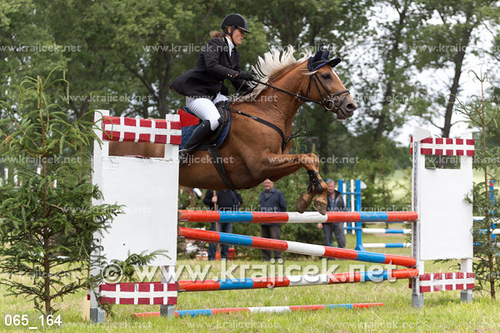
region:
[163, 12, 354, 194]
person riding jumping horse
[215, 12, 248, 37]
black hat of horse rider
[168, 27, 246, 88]
black jacket of horse rider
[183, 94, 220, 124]
white pants of horse rider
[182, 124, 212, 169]
black boots of rider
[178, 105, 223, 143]
black saddle on the horse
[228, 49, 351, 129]
black reins of horse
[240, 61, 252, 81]
black gloves of rider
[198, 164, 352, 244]
people watching the horse jump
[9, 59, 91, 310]
tree beside barrier horse is jumping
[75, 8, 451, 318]
woman jumping hurdles on a brown horse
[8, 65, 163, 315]
green leaves growing on thin tree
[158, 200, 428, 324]
red blue and white piping for horse to jump over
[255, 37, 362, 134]
brown head of horse with blonde mane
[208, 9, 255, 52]
black helmet with brown pony tail sticking out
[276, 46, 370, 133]
black leather and metal bridle on horse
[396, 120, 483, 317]
sides painted to look like brick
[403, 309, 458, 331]
yellow and green grass growing on the ground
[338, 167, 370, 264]
royal blue painted posts sticking out of ground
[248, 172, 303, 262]
man in jacket watching horse jumping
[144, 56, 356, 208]
brown horse jumps over bars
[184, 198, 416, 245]
red white and blue bars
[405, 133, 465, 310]
red and white gates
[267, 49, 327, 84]
horse has white mane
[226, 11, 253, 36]
woman has brown cap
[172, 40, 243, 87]
woman has black riding jacket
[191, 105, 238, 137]
woman has white pants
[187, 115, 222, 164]
woman has black boots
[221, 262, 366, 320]
green grass under gates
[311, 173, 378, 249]
blue fence in background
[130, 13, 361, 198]
Woman is riding a horse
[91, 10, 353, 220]
Woman is riding a brown horse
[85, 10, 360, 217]
Woman is jumping over hurdles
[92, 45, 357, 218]
Horse is jumping over hurdles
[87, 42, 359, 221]
Brown horse is jumping over hurdles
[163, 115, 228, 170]
Woman is wearing boots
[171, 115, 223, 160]
Woman is wearing black boots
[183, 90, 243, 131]
Woman is wearing pants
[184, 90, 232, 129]
Woman is wearing white pants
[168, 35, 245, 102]
Woman is wearing a blazer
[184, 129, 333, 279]
Horse jumping over obstacle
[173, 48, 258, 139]
Jockey on a horse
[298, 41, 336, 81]
horse wearing a black hat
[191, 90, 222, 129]
jockey wearing white pants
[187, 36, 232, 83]
jockey wearing black jacket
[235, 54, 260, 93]
jockey wearing gloves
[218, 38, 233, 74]
jockey wearing a white shirt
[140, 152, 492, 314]
red white and blue obstacle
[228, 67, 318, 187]
woman riding a horse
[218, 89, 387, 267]
horse jumping over a pole